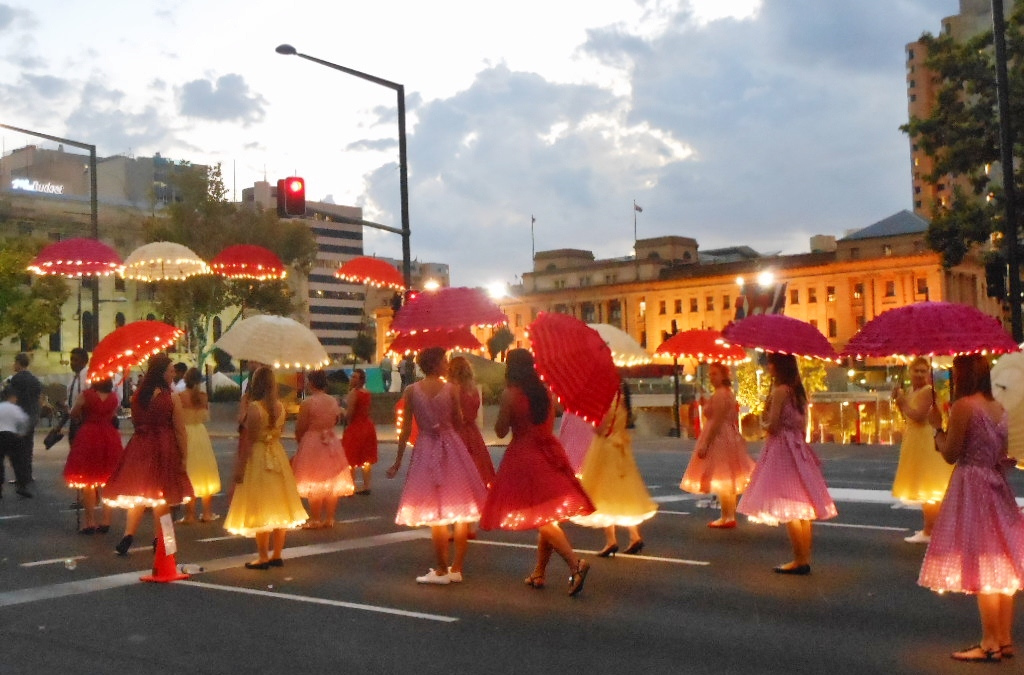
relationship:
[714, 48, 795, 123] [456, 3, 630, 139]
blue and white sky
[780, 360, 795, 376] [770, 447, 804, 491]
brown haired girl in pink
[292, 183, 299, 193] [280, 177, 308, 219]
red traffic light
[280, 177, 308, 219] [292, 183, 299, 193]
light with red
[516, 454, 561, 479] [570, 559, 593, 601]
red dress and flats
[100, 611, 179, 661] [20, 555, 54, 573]
grey roads with lines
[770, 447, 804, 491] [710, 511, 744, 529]
pink dress and red shoes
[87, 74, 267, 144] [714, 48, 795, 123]
clouds are dark blue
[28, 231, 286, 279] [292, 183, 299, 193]
umbrellas are white and red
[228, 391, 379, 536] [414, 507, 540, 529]
dresses have lights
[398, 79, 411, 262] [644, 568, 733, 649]
pole on street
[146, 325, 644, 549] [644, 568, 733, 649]
people celebrating on street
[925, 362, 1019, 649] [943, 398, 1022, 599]
girl wearing pink dress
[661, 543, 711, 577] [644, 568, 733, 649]
white lines on street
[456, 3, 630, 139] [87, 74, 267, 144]
sky dark with clouds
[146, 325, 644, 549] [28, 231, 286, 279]
people with umbrellas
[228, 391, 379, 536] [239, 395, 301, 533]
dresses are red pink and yellow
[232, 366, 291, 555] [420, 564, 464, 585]
girl has white shoes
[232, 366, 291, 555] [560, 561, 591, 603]
girl has on sandals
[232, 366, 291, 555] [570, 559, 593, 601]
girl wears flats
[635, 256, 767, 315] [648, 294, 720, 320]
building has windows